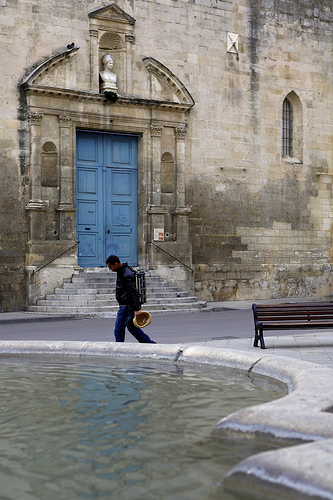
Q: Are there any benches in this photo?
A: Yes, there is a bench.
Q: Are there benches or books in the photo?
A: Yes, there is a bench.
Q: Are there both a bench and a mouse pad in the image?
A: No, there is a bench but no mouse pads.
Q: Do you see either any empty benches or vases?
A: Yes, there is an empty bench.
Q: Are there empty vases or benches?
A: Yes, there is an empty bench.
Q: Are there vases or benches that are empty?
A: Yes, the bench is empty.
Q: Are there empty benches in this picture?
A: Yes, there is an empty bench.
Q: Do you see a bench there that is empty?
A: Yes, there is a bench that is empty.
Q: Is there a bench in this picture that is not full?
A: Yes, there is a empty bench.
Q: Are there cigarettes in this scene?
A: No, there are no cigarettes.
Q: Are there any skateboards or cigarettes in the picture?
A: No, there are no cigarettes or skateboards.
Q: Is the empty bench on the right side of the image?
A: Yes, the bench is on the right of the image.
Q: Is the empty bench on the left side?
A: No, the bench is on the right of the image.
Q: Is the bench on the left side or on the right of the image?
A: The bench is on the right of the image.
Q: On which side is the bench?
A: The bench is on the right of the image.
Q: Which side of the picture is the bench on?
A: The bench is on the right of the image.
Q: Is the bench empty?
A: Yes, the bench is empty.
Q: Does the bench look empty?
A: Yes, the bench is empty.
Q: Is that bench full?
A: No, the bench is empty.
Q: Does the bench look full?
A: No, the bench is empty.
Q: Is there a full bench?
A: No, there is a bench but it is empty.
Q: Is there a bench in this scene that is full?
A: No, there is a bench but it is empty.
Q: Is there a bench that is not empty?
A: No, there is a bench but it is empty.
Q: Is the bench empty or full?
A: The bench is empty.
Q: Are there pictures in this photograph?
A: No, there are no pictures.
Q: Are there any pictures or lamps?
A: No, there are no pictures or lamps.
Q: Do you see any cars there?
A: No, there are no cars.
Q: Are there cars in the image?
A: No, there are no cars.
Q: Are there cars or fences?
A: No, there are no cars or fences.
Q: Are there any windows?
A: Yes, there is a window.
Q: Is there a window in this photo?
A: Yes, there is a window.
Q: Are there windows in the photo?
A: Yes, there is a window.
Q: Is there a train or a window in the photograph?
A: Yes, there is a window.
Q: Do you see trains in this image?
A: No, there are no trains.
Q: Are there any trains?
A: No, there are no trains.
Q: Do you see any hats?
A: Yes, there is a hat.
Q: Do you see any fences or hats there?
A: Yes, there is a hat.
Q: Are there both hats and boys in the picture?
A: No, there is a hat but no boys.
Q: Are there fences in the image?
A: No, there are no fences.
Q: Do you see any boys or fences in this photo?
A: No, there are no fences or boys.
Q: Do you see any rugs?
A: No, there are no rugs.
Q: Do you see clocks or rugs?
A: No, there are no rugs or clocks.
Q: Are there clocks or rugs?
A: No, there are no rugs or clocks.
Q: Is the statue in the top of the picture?
A: Yes, the statue is in the top of the image.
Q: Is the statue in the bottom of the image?
A: No, the statue is in the top of the image.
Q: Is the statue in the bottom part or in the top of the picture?
A: The statue is in the top of the image.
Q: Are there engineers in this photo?
A: No, there are no engineers.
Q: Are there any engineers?
A: No, there are no engineers.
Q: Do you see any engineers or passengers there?
A: No, there are no engineers or passengers.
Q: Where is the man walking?
A: The man is walking on the sidewalk.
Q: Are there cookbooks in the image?
A: No, there are no cookbooks.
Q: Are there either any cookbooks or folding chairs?
A: No, there are no cookbooks or folding chairs.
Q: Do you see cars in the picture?
A: No, there are no cars.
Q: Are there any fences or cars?
A: No, there are no cars or fences.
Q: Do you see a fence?
A: No, there are no fences.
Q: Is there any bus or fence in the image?
A: No, there are no fences or buses.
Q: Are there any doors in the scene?
A: Yes, there are doors.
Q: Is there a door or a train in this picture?
A: Yes, there are doors.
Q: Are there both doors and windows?
A: Yes, there are both doors and windows.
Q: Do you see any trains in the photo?
A: No, there are no trains.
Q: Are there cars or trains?
A: No, there are no trains or cars.